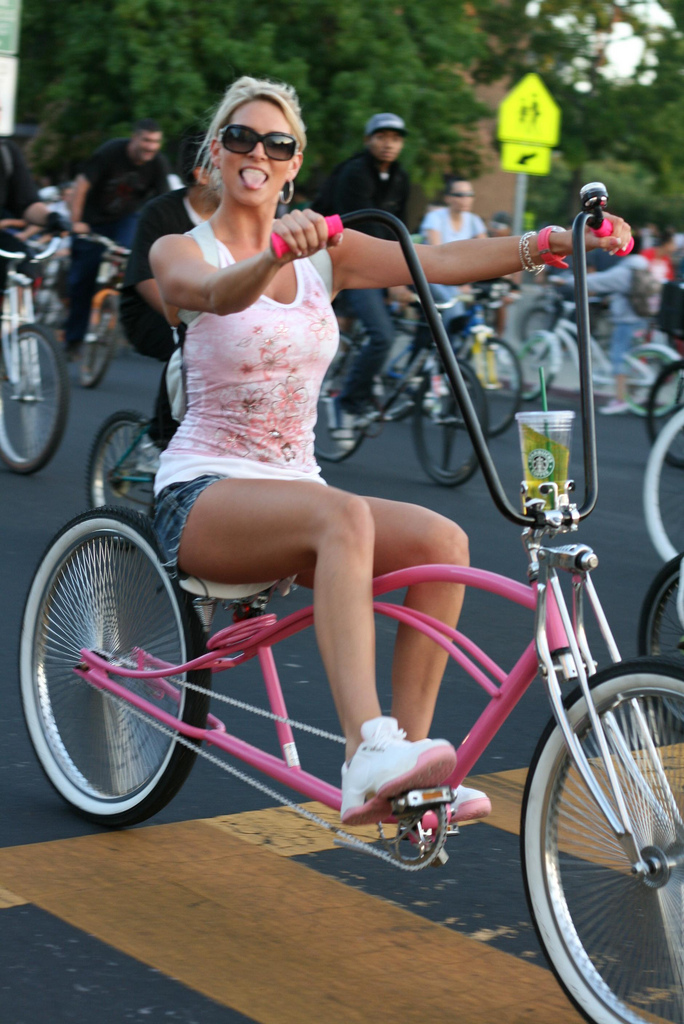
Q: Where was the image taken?
A: It was taken at the road.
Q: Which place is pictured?
A: It is a road.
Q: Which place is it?
A: It is a road.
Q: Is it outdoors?
A: Yes, it is outdoors.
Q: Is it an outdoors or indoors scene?
A: It is outdoors.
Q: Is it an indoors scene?
A: No, it is outdoors.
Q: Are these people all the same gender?
A: No, they are both male and female.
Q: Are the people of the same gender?
A: No, they are both male and female.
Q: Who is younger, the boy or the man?
A: The boy is younger than the man.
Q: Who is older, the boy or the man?
A: The man is older than the boy.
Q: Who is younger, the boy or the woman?
A: The boy is younger than the woman.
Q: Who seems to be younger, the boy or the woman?
A: The boy is younger than the woman.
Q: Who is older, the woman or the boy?
A: The woman is older than the boy.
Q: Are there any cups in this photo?
A: Yes, there is a cup.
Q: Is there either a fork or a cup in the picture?
A: Yes, there is a cup.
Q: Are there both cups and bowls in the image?
A: No, there is a cup but no bowls.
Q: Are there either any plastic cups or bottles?
A: Yes, there is a plastic cup.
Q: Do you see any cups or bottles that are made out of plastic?
A: Yes, the cup is made of plastic.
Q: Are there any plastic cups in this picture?
A: Yes, there is a cup that is made of plastic.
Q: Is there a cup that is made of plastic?
A: Yes, there is a cup that is made of plastic.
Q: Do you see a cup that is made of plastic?
A: Yes, there is a cup that is made of plastic.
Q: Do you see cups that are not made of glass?
A: Yes, there is a cup that is made of plastic.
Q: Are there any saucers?
A: No, there are no saucers.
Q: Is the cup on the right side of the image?
A: Yes, the cup is on the right of the image.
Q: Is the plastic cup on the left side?
A: No, the cup is on the right of the image.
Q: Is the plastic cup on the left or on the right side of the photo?
A: The cup is on the right of the image.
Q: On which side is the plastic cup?
A: The cup is on the right of the image.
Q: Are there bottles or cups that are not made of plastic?
A: No, there is a cup but it is made of plastic.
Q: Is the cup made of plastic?
A: Yes, the cup is made of plastic.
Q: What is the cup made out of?
A: The cup is made of plastic.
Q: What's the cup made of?
A: The cup is made of plastic.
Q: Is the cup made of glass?
A: No, the cup is made of plastic.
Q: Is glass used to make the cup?
A: No, the cup is made of plastic.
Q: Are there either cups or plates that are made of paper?
A: No, there is a cup but it is made of plastic.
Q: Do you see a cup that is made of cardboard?
A: No, there is a cup but it is made of plastic.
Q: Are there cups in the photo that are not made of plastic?
A: No, there is a cup but it is made of plastic.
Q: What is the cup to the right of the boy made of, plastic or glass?
A: The cup is made of plastic.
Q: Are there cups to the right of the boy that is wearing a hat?
A: Yes, there is a cup to the right of the boy.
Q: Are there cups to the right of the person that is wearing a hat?
A: Yes, there is a cup to the right of the boy.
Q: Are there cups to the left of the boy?
A: No, the cup is to the right of the boy.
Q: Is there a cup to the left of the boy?
A: No, the cup is to the right of the boy.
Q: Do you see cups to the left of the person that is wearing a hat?
A: No, the cup is to the right of the boy.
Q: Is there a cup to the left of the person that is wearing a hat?
A: No, the cup is to the right of the boy.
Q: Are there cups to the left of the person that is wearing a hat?
A: No, the cup is to the right of the boy.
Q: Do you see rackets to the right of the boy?
A: No, there is a cup to the right of the boy.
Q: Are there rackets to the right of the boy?
A: No, there is a cup to the right of the boy.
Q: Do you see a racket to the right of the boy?
A: No, there is a cup to the right of the boy.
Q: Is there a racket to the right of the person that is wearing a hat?
A: No, there is a cup to the right of the boy.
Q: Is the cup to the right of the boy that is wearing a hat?
A: Yes, the cup is to the right of the boy.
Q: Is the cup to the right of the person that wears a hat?
A: Yes, the cup is to the right of the boy.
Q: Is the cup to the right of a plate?
A: No, the cup is to the right of the boy.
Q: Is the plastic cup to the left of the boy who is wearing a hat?
A: No, the cup is to the right of the boy.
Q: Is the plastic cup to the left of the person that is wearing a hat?
A: No, the cup is to the right of the boy.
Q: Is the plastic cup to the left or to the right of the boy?
A: The cup is to the right of the boy.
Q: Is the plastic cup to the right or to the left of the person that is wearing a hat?
A: The cup is to the right of the boy.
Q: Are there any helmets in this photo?
A: No, there are no helmets.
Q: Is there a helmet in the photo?
A: No, there are no helmets.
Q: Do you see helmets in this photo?
A: No, there are no helmets.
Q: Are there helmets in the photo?
A: No, there are no helmets.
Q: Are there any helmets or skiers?
A: No, there are no helmets or skiers.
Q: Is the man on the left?
A: Yes, the man is on the left of the image.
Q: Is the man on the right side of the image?
A: No, the man is on the left of the image.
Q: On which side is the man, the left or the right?
A: The man is on the left of the image.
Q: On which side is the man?
A: The man is on the left of the image.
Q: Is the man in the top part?
A: Yes, the man is in the top of the image.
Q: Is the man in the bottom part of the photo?
A: No, the man is in the top of the image.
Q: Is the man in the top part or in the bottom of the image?
A: The man is in the top of the image.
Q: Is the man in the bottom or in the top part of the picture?
A: The man is in the top of the image.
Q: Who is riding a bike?
A: The man is riding a bike.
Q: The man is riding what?
A: The man is riding a bike.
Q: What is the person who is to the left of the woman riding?
A: The man is riding a bike.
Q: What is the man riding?
A: The man is riding a bike.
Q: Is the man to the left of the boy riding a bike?
A: Yes, the man is riding a bike.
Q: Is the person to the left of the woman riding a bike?
A: Yes, the man is riding a bike.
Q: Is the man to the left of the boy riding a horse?
A: No, the man is riding a bike.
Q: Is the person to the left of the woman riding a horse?
A: No, the man is riding a bike.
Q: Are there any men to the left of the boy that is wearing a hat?
A: Yes, there is a man to the left of the boy.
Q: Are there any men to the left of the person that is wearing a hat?
A: Yes, there is a man to the left of the boy.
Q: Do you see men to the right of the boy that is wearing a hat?
A: No, the man is to the left of the boy.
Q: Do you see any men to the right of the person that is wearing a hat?
A: No, the man is to the left of the boy.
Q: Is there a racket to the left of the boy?
A: No, there is a man to the left of the boy.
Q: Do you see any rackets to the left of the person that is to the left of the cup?
A: No, there is a man to the left of the boy.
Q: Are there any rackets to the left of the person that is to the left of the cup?
A: No, there is a man to the left of the boy.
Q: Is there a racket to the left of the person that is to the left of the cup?
A: No, there is a man to the left of the boy.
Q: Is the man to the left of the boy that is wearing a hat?
A: Yes, the man is to the left of the boy.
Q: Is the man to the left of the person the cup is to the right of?
A: Yes, the man is to the left of the boy.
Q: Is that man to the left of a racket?
A: No, the man is to the left of the boy.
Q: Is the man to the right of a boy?
A: No, the man is to the left of a boy.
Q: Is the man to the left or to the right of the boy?
A: The man is to the left of the boy.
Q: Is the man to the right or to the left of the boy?
A: The man is to the left of the boy.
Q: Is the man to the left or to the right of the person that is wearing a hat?
A: The man is to the left of the boy.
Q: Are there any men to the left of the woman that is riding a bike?
A: Yes, there is a man to the left of the woman.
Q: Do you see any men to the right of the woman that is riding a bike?
A: No, the man is to the left of the woman.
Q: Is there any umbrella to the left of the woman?
A: No, there is a man to the left of the woman.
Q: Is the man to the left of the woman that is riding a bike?
A: Yes, the man is to the left of the woman.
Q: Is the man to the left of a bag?
A: No, the man is to the left of the woman.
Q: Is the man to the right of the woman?
A: No, the man is to the left of the woman.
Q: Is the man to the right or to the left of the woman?
A: The man is to the left of the woman.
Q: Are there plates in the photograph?
A: No, there are no plates.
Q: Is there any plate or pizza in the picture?
A: No, there are no plates or pizzas.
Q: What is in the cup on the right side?
A: The straw is in the cup.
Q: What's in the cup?
A: The straw is in the cup.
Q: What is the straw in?
A: The straw is in the cup.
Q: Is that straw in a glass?
A: No, the straw is in a cup.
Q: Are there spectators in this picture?
A: No, there are no spectators.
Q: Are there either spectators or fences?
A: No, there are no spectators or fences.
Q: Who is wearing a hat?
A: The boy is wearing a hat.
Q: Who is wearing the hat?
A: The boy is wearing a hat.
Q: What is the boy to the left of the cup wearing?
A: The boy is wearing a hat.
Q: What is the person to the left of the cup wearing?
A: The boy is wearing a hat.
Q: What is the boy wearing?
A: The boy is wearing a hat.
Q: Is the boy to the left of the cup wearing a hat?
A: Yes, the boy is wearing a hat.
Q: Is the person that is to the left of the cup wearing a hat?
A: Yes, the boy is wearing a hat.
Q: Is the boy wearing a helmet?
A: No, the boy is wearing a hat.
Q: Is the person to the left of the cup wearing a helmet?
A: No, the boy is wearing a hat.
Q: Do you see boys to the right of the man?
A: Yes, there is a boy to the right of the man.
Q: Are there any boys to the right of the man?
A: Yes, there is a boy to the right of the man.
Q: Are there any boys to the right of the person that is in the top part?
A: Yes, there is a boy to the right of the man.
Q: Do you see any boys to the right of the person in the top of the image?
A: Yes, there is a boy to the right of the man.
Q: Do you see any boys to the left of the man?
A: No, the boy is to the right of the man.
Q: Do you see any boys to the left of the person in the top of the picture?
A: No, the boy is to the right of the man.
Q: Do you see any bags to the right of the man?
A: No, there is a boy to the right of the man.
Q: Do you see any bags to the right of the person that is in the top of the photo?
A: No, there is a boy to the right of the man.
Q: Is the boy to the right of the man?
A: Yes, the boy is to the right of the man.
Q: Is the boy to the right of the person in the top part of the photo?
A: Yes, the boy is to the right of the man.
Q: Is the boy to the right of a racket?
A: No, the boy is to the right of the man.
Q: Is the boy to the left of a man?
A: No, the boy is to the right of a man.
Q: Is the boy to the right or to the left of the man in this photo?
A: The boy is to the right of the man.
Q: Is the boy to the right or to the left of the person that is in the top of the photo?
A: The boy is to the right of the man.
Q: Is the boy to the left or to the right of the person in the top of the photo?
A: The boy is to the right of the man.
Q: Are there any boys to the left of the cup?
A: Yes, there is a boy to the left of the cup.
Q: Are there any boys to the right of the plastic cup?
A: No, the boy is to the left of the cup.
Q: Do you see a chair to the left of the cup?
A: No, there is a boy to the left of the cup.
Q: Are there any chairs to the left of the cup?
A: No, there is a boy to the left of the cup.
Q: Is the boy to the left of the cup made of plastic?
A: Yes, the boy is to the left of the cup.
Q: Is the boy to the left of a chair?
A: No, the boy is to the left of the cup.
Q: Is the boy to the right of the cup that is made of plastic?
A: No, the boy is to the left of the cup.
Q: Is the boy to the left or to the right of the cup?
A: The boy is to the left of the cup.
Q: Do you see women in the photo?
A: Yes, there is a woman.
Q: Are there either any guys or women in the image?
A: Yes, there is a woman.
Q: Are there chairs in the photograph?
A: No, there are no chairs.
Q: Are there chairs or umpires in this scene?
A: No, there are no chairs or umpires.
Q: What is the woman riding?
A: The woman is riding a bike.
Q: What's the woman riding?
A: The woman is riding a bike.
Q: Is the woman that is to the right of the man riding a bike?
A: Yes, the woman is riding a bike.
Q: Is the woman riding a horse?
A: No, the woman is riding a bike.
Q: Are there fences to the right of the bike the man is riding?
A: No, there is a woman to the right of the bike.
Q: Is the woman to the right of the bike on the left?
A: Yes, the woman is to the right of the bike.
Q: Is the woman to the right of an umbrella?
A: No, the woman is to the right of the bike.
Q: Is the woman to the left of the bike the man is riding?
A: No, the woman is to the right of the bike.